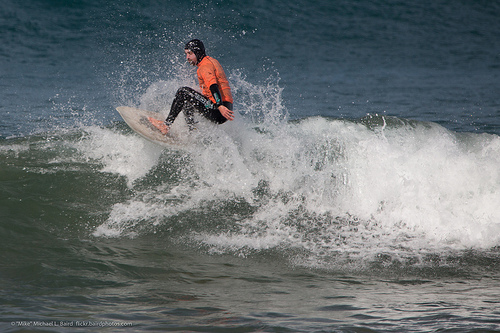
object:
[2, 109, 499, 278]
wave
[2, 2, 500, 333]
ocean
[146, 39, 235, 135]
man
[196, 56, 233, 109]
shirt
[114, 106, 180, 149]
surfboard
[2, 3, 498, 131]
water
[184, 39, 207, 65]
hat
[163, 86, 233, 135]
pants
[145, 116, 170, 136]
foot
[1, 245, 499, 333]
water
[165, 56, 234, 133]
wet suit